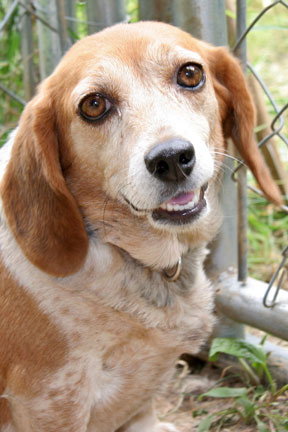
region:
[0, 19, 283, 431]
A brown and white dog.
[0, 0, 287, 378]
A gray chainlink fence.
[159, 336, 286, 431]
A small patch of plants.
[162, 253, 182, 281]
A silver colored d-ring.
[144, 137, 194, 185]
A black dog nose.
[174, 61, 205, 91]
A brown dog eye.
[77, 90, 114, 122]
A brown colored eye.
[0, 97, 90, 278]
A brown floppy ear.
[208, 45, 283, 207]
A brown dog ear.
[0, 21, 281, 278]
Brown and white dog head.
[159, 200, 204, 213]
teeth in mouth of small dog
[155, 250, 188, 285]
silver metal ring on dog collar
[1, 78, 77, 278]
brown ear on dog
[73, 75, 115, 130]
orange eye on dog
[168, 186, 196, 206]
pink tongue in mouth of small dog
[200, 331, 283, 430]
small green plant on ground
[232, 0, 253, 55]
silver metal fence post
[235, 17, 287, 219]
grey chain link fencing behind dog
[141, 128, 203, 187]
black nose on dog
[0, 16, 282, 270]
white and brown dog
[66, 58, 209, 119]
two brown round dog eyes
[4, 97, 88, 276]
one long brown dog ear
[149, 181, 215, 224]
one open dog mouth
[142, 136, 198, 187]
one black shiny dog nose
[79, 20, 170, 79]
white and brown top of dog head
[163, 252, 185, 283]
partial view of round shiny dog tag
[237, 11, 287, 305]
section of chain link fence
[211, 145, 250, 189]
several white dog whiskers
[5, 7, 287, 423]
brown and white dog in front of fence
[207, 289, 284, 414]
bit of greenery by fence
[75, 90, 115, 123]
A dog's light brown eye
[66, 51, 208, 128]
A pair of dog's eyes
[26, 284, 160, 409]
The dog is a light brown color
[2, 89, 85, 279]
The dog has a long ear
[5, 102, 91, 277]
The dog has a long brown ear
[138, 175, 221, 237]
The dog's mouth is open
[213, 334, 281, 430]
Vegetation at the bottom of the picture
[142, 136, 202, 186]
The dog has a black nose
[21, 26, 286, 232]
The dog is facing the camera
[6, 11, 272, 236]
The dog is looking at the camera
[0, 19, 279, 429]
a dog looking into the camera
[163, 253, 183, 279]
a tag hanging from the dog's collar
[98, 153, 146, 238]
whiskers on the dog's face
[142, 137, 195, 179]
a wet black nose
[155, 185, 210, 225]
the black bottom lip of the dog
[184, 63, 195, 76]
a reflection of light in the dog's eye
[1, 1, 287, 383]
a chain link fence behind the dog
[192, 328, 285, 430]
a weed growing in the ground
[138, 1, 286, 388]
the metal pole frame of the fence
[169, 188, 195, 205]
the dog's tongue slightly sticking out